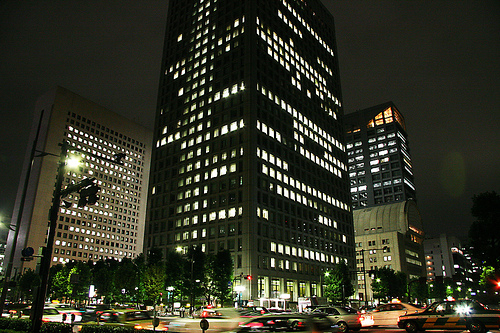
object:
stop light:
[244, 272, 254, 282]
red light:
[247, 275, 252, 279]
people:
[496, 178, 499, 179]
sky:
[329, 3, 498, 104]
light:
[62, 150, 91, 178]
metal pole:
[36, 128, 99, 325]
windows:
[139, 1, 346, 281]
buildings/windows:
[0, 0, 485, 309]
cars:
[0, 298, 499, 331]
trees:
[207, 241, 246, 316]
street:
[11, 314, 484, 331]